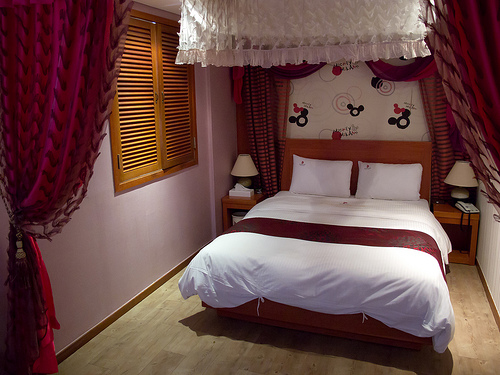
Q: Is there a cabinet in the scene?
A: No, there are no cabinets.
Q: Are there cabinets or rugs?
A: No, there are no cabinets or rugs.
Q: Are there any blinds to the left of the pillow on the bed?
A: Yes, there are blinds to the left of the pillow.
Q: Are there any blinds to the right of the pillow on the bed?
A: No, the blinds are to the left of the pillow.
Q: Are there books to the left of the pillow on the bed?
A: No, there are blinds to the left of the pillow.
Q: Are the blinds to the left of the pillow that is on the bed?
A: Yes, the blinds are to the left of the pillow.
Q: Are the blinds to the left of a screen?
A: No, the blinds are to the left of the pillow.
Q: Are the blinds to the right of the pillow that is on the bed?
A: No, the blinds are to the left of the pillow.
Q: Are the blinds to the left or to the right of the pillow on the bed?
A: The blinds are to the left of the pillow.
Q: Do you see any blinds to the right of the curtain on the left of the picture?
A: Yes, there are blinds to the right of the curtain.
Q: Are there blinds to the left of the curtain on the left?
A: No, the blinds are to the right of the curtain.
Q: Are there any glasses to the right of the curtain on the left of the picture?
A: No, there are blinds to the right of the curtain.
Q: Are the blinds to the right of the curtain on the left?
A: Yes, the blinds are to the right of the curtain.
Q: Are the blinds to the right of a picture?
A: No, the blinds are to the right of the curtain.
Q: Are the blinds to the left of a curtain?
A: No, the blinds are to the right of a curtain.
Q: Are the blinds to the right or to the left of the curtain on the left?
A: The blinds are to the right of the curtain.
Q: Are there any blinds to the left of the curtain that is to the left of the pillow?
A: Yes, there are blinds to the left of the curtain.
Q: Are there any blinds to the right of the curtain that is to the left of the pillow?
A: No, the blinds are to the left of the curtain.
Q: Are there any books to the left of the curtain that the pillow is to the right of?
A: No, there are blinds to the left of the curtain.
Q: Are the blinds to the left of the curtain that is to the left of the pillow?
A: Yes, the blinds are to the left of the curtain.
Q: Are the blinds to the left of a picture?
A: No, the blinds are to the left of the curtain.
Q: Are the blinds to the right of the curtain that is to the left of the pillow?
A: No, the blinds are to the left of the curtain.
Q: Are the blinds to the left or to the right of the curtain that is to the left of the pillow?
A: The blinds are to the left of the curtain.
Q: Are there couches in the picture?
A: No, there are no couches.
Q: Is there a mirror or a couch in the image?
A: No, there are no couches or mirrors.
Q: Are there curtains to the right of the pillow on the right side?
A: Yes, there is a curtain to the right of the pillow.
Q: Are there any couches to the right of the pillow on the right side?
A: No, there is a curtain to the right of the pillow.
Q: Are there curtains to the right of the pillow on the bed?
A: Yes, there is a curtain to the right of the pillow.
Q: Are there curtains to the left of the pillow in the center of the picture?
A: No, the curtain is to the right of the pillow.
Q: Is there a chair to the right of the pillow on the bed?
A: No, there is a curtain to the right of the pillow.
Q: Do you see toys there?
A: No, there are no toys.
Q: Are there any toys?
A: No, there are no toys.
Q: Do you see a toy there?
A: No, there are no toys.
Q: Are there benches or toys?
A: No, there are no toys or benches.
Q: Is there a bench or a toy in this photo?
A: No, there are no toys or benches.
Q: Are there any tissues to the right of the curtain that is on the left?
A: Yes, there are tissues to the right of the curtain.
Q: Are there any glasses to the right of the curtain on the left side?
A: No, there are tissues to the right of the curtain.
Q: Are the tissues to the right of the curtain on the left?
A: Yes, the tissues are to the right of the curtain.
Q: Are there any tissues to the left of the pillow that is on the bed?
A: Yes, there are tissues to the left of the pillow.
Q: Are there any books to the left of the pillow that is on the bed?
A: No, there are tissues to the left of the pillow.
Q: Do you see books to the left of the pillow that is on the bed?
A: No, there are tissues to the left of the pillow.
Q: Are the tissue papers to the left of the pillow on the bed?
A: Yes, the tissue papers are to the left of the pillow.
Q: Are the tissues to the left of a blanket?
A: No, the tissues are to the left of the pillow.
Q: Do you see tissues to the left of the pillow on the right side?
A: Yes, there are tissues to the left of the pillow.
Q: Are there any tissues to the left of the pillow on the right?
A: Yes, there are tissues to the left of the pillow.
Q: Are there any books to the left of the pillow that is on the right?
A: No, there are tissues to the left of the pillow.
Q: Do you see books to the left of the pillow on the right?
A: No, there are tissues to the left of the pillow.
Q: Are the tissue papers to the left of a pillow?
A: Yes, the tissue papers are to the left of a pillow.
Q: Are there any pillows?
A: Yes, there is a pillow.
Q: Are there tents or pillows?
A: Yes, there is a pillow.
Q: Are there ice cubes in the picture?
A: No, there are no ice cubes.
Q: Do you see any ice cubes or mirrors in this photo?
A: No, there are no ice cubes or mirrors.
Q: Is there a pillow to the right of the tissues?
A: Yes, there is a pillow to the right of the tissues.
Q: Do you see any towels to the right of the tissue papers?
A: No, there is a pillow to the right of the tissue papers.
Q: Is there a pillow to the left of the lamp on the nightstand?
A: Yes, there is a pillow to the left of the lamp.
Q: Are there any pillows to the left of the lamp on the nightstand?
A: Yes, there is a pillow to the left of the lamp.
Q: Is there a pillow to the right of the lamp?
A: No, the pillow is to the left of the lamp.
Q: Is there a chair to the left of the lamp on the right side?
A: No, there is a pillow to the left of the lamp.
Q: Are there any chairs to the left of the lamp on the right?
A: No, there is a pillow to the left of the lamp.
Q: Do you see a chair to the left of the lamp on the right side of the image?
A: No, there is a pillow to the left of the lamp.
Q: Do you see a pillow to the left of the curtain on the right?
A: Yes, there is a pillow to the left of the curtain.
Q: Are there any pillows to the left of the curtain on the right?
A: Yes, there is a pillow to the left of the curtain.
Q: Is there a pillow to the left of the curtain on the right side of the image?
A: Yes, there is a pillow to the left of the curtain.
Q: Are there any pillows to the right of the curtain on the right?
A: No, the pillow is to the left of the curtain.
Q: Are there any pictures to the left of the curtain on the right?
A: No, there is a pillow to the left of the curtain.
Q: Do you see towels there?
A: No, there are no towels.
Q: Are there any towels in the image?
A: No, there are no towels.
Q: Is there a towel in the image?
A: No, there are no towels.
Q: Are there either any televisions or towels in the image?
A: No, there are no towels or televisions.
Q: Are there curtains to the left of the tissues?
A: Yes, there is a curtain to the left of the tissues.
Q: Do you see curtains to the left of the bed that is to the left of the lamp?
A: Yes, there is a curtain to the left of the bed.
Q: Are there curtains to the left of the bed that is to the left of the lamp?
A: Yes, there is a curtain to the left of the bed.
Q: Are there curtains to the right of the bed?
A: No, the curtain is to the left of the bed.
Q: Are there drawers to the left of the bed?
A: No, there is a curtain to the left of the bed.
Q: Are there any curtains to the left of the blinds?
A: Yes, there is a curtain to the left of the blinds.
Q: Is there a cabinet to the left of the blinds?
A: No, there is a curtain to the left of the blinds.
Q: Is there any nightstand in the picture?
A: Yes, there is a nightstand.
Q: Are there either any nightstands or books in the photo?
A: Yes, there is a nightstand.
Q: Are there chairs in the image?
A: No, there are no chairs.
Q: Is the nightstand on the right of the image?
A: Yes, the nightstand is on the right of the image.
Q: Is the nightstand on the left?
A: No, the nightstand is on the right of the image.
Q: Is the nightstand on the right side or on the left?
A: The nightstand is on the right of the image.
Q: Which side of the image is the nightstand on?
A: The nightstand is on the right of the image.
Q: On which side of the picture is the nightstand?
A: The nightstand is on the right of the image.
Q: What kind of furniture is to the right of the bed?
A: The piece of furniture is a nightstand.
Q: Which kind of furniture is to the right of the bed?
A: The piece of furniture is a nightstand.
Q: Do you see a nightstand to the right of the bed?
A: Yes, there is a nightstand to the right of the bed.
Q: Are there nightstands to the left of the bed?
A: No, the nightstand is to the right of the bed.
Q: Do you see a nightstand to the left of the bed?
A: No, the nightstand is to the right of the bed.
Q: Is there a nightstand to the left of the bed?
A: No, the nightstand is to the right of the bed.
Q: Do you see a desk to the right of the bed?
A: No, there is a nightstand to the right of the bed.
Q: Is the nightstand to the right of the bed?
A: Yes, the nightstand is to the right of the bed.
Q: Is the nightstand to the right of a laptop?
A: No, the nightstand is to the right of the bed.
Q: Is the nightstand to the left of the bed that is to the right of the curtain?
A: No, the nightstand is to the right of the bed.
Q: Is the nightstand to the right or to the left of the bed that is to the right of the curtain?
A: The nightstand is to the right of the bed.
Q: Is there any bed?
A: Yes, there is a bed.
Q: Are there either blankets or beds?
A: Yes, there is a bed.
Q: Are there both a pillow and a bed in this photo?
A: Yes, there are both a bed and a pillow.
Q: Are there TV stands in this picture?
A: No, there are no TV stands.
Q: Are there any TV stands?
A: No, there are no TV stands.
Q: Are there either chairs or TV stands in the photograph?
A: No, there are no TV stands or chairs.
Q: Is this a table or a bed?
A: This is a bed.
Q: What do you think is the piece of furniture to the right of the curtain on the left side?
A: The piece of furniture is a bed.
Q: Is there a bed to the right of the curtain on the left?
A: Yes, there is a bed to the right of the curtain.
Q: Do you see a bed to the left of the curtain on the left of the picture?
A: No, the bed is to the right of the curtain.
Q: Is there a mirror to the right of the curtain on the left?
A: No, there is a bed to the right of the curtain.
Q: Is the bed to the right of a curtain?
A: Yes, the bed is to the right of a curtain.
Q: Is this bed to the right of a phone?
A: No, the bed is to the right of a curtain.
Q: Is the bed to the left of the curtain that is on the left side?
A: No, the bed is to the right of the curtain.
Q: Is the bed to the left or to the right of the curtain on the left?
A: The bed is to the right of the curtain.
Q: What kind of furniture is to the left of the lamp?
A: The piece of furniture is a bed.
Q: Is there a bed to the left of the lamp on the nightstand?
A: Yes, there is a bed to the left of the lamp.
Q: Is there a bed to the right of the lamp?
A: No, the bed is to the left of the lamp.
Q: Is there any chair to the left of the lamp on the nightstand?
A: No, there is a bed to the left of the lamp.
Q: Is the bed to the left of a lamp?
A: Yes, the bed is to the left of a lamp.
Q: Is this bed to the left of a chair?
A: No, the bed is to the left of a lamp.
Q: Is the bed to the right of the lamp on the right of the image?
A: No, the bed is to the left of the lamp.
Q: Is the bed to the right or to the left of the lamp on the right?
A: The bed is to the left of the lamp.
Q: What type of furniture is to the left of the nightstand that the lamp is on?
A: The piece of furniture is a bed.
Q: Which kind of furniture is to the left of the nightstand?
A: The piece of furniture is a bed.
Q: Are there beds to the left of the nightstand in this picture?
A: Yes, there is a bed to the left of the nightstand.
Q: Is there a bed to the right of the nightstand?
A: No, the bed is to the left of the nightstand.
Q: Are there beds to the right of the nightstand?
A: No, the bed is to the left of the nightstand.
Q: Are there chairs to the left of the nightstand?
A: No, there is a bed to the left of the nightstand.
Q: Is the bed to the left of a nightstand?
A: Yes, the bed is to the left of a nightstand.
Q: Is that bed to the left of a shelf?
A: No, the bed is to the left of a nightstand.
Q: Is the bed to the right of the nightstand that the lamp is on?
A: No, the bed is to the left of the nightstand.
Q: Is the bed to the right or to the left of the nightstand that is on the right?
A: The bed is to the left of the nightstand.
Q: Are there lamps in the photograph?
A: Yes, there is a lamp.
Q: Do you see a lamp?
A: Yes, there is a lamp.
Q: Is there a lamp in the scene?
A: Yes, there is a lamp.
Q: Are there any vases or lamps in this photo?
A: Yes, there is a lamp.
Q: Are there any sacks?
A: No, there are no sacks.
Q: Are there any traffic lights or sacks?
A: No, there are no sacks or traffic lights.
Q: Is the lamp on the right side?
A: Yes, the lamp is on the right of the image.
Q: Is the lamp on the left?
A: No, the lamp is on the right of the image.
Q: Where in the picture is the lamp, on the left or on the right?
A: The lamp is on the right of the image.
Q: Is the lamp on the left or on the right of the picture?
A: The lamp is on the right of the image.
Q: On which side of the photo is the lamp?
A: The lamp is on the right of the image.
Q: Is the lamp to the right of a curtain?
A: Yes, the lamp is to the right of a curtain.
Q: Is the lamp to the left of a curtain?
A: No, the lamp is to the right of a curtain.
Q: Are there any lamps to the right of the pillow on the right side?
A: Yes, there is a lamp to the right of the pillow.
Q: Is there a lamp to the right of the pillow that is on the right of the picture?
A: Yes, there is a lamp to the right of the pillow.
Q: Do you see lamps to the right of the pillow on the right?
A: Yes, there is a lamp to the right of the pillow.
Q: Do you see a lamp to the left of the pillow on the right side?
A: No, the lamp is to the right of the pillow.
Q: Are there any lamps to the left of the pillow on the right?
A: No, the lamp is to the right of the pillow.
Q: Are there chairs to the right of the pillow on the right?
A: No, there is a lamp to the right of the pillow.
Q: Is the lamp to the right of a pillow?
A: Yes, the lamp is to the right of a pillow.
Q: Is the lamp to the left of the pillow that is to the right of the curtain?
A: No, the lamp is to the right of the pillow.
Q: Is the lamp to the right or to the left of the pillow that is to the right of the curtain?
A: The lamp is to the right of the pillow.